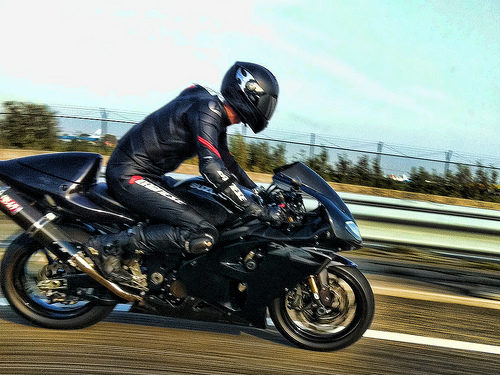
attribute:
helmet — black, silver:
[221, 62, 279, 134]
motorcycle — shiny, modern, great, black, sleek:
[0, 151, 375, 351]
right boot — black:
[86, 221, 145, 282]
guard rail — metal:
[97, 166, 500, 253]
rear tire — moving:
[0, 230, 117, 329]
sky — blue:
[0, 0, 498, 180]